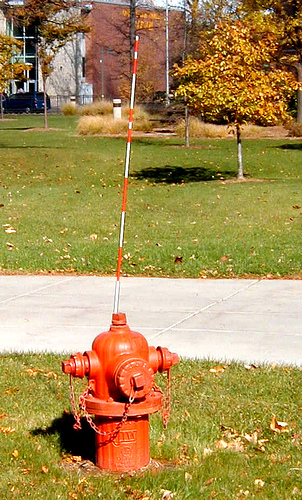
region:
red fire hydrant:
[57, 311, 195, 473]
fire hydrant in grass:
[42, 306, 194, 477]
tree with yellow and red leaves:
[167, 17, 299, 188]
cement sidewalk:
[4, 263, 300, 361]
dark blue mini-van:
[0, 87, 60, 116]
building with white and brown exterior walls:
[5, 0, 193, 116]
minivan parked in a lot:
[0, 82, 56, 116]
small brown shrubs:
[61, 97, 229, 141]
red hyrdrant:
[49, 305, 189, 475]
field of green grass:
[1, 111, 301, 271]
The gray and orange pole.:
[92, 33, 136, 325]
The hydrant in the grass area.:
[57, 307, 185, 470]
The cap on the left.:
[62, 352, 86, 380]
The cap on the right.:
[150, 346, 181, 368]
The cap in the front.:
[117, 361, 153, 398]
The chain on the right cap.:
[161, 366, 171, 425]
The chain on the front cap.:
[81, 382, 134, 436]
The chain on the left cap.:
[63, 372, 91, 429]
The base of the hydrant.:
[95, 419, 151, 470]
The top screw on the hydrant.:
[110, 313, 125, 323]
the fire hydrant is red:
[62, 312, 179, 471]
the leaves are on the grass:
[2, 352, 300, 498]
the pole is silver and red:
[113, 35, 139, 315]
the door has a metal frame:
[7, 17, 38, 92]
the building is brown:
[84, 3, 182, 104]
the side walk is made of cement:
[0, 274, 300, 366]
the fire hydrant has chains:
[70, 363, 171, 434]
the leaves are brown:
[0, 358, 301, 499]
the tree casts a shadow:
[129, 164, 242, 184]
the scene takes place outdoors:
[0, 0, 300, 498]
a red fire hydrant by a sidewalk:
[58, 310, 183, 480]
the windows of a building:
[14, 22, 39, 56]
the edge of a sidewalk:
[174, 266, 298, 290]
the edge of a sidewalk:
[197, 355, 299, 368]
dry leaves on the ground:
[216, 412, 265, 462]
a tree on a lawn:
[171, 15, 296, 184]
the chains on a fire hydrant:
[64, 381, 132, 448]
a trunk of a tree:
[232, 127, 251, 183]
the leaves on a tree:
[212, 48, 260, 111]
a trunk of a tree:
[182, 106, 198, 149]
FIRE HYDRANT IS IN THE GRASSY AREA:
[58, 318, 186, 484]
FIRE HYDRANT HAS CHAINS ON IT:
[54, 356, 179, 440]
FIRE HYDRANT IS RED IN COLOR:
[61, 309, 191, 481]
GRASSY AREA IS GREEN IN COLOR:
[179, 374, 292, 492]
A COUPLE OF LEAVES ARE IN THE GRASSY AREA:
[181, 407, 296, 462]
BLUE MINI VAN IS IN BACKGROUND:
[0, 86, 55, 114]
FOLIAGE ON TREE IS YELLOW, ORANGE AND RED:
[174, 16, 294, 147]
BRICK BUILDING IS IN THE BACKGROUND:
[0, 3, 178, 109]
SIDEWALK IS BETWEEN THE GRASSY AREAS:
[8, 278, 289, 355]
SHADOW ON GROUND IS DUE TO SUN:
[125, 149, 265, 199]